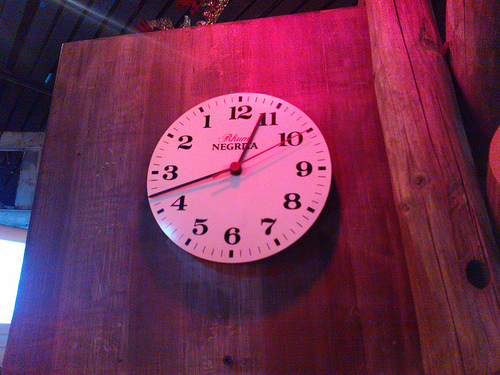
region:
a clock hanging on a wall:
[126, 34, 350, 286]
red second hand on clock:
[241, 103, 318, 190]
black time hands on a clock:
[156, 101, 278, 221]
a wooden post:
[343, 10, 450, 347]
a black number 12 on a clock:
[230, 83, 263, 129]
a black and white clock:
[123, 55, 332, 309]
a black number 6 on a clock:
[210, 212, 244, 273]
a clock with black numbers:
[102, 64, 374, 306]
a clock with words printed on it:
[157, 70, 324, 290]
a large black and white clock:
[143, 70, 349, 274]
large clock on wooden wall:
[145, 94, 331, 264]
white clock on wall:
[147, 91, 329, 264]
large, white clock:
[145, 91, 333, 267]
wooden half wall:
[1, 3, 498, 373]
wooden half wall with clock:
[2, 5, 495, 373]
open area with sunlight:
[0, 234, 30, 324]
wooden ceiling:
[0, 1, 363, 228]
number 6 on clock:
[225, 228, 241, 245]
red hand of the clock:
[210, 128, 307, 181]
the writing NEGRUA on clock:
[212, 142, 258, 151]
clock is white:
[144, 94, 339, 259]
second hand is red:
[230, 133, 300, 169]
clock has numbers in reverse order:
[140, 83, 352, 266]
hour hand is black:
[235, 112, 267, 171]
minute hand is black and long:
[148, 160, 237, 203]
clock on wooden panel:
[48, 37, 421, 371]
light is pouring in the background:
[0, 238, 32, 332]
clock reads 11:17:
[153, 95, 262, 198]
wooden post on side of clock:
[353, 7, 490, 374]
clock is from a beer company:
[207, 131, 262, 157]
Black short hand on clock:
[231, 109, 268, 171]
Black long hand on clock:
[144, 157, 231, 203]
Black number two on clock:
[168, 131, 202, 157]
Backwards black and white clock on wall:
[138, 78, 335, 307]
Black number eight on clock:
[275, 182, 310, 221]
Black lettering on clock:
[207, 142, 262, 152]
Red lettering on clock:
[216, 134, 260, 142]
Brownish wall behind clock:
[78, 64, 159, 125]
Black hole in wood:
[454, 238, 496, 309]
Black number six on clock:
[221, 219, 243, 265]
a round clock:
[123, 83, 346, 275]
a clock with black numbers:
[138, 71, 343, 263]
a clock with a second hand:
[121, 87, 347, 266]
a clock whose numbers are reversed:
[141, 79, 353, 272]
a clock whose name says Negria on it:
[138, 77, 365, 322]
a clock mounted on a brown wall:
[0, 4, 498, 370]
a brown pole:
[341, 4, 498, 369]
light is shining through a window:
[0, 227, 36, 324]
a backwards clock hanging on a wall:
[135, 72, 342, 292]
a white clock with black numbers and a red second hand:
[80, 83, 352, 285]